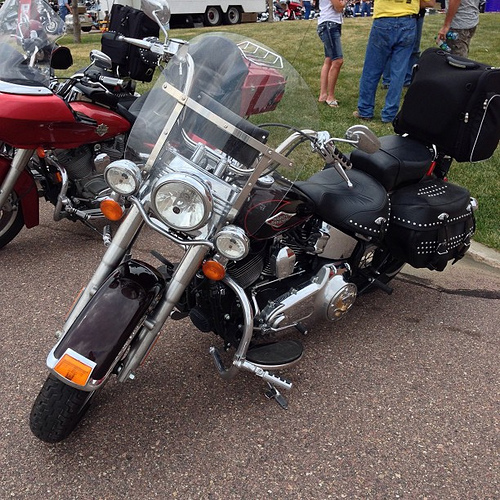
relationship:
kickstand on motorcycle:
[201, 343, 297, 414] [26, 5, 499, 447]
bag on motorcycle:
[386, 177, 477, 270] [29, 99, 470, 440]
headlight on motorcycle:
[144, 168, 221, 239] [26, 5, 499, 447]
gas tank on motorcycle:
[238, 173, 318, 245] [26, 5, 499, 447]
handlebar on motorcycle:
[268, 128, 353, 190] [26, 5, 499, 447]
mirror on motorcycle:
[343, 120, 382, 155] [26, 5, 499, 447]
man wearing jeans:
[346, 1, 438, 123] [338, 16, 418, 120]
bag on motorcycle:
[386, 177, 477, 270] [26, 5, 499, 447]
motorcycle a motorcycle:
[27, 0, 480, 446] [27, 0, 480, 446]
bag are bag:
[386, 177, 477, 270] [386, 177, 477, 270]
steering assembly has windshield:
[29, 31, 381, 443] [105, 29, 316, 209]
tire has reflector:
[27, 259, 167, 445] [44, 341, 100, 391]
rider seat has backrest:
[348, 132, 460, 181] [367, 24, 498, 171]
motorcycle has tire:
[27, 32, 480, 446] [27, 259, 167, 445]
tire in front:
[27, 259, 167, 445] [39, 215, 176, 445]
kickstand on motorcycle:
[206, 358, 305, 398] [26, 5, 499, 447]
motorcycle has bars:
[27, 0, 480, 446] [118, 31, 359, 165]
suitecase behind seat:
[392, 39, 498, 179] [304, 104, 496, 285]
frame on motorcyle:
[8, 98, 132, 210] [6, 53, 143, 256]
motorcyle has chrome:
[6, 53, 143, 256] [49, 160, 75, 199]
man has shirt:
[351, 0, 437, 124] [366, 0, 424, 23]